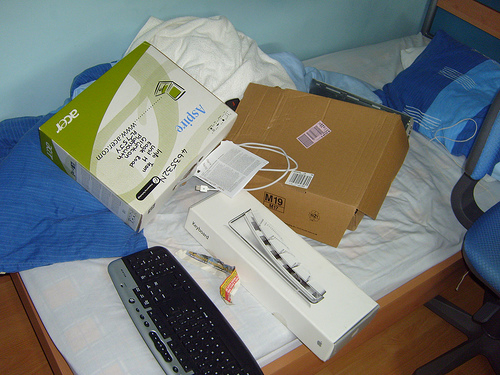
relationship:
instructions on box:
[191, 140, 270, 198] [219, 81, 413, 247]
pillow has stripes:
[370, 29, 499, 157] [439, 64, 480, 94]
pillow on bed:
[370, 29, 499, 157] [306, 29, 499, 298]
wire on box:
[192, 140, 304, 202] [187, 183, 382, 362]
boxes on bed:
[35, 42, 411, 360] [306, 29, 499, 298]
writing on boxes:
[51, 106, 84, 134] [35, 42, 241, 233]